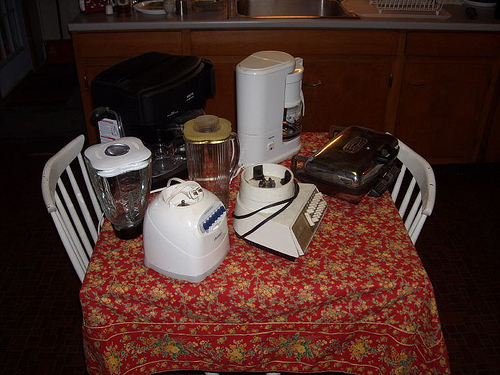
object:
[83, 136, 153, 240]
appliances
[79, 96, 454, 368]
table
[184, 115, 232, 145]
lid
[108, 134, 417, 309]
cloth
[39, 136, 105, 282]
chair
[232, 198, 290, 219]
cord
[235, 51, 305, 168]
coffee maker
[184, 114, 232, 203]
blender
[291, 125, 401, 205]
waffle maker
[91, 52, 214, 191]
espresso machine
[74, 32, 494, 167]
door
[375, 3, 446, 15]
dish stainer